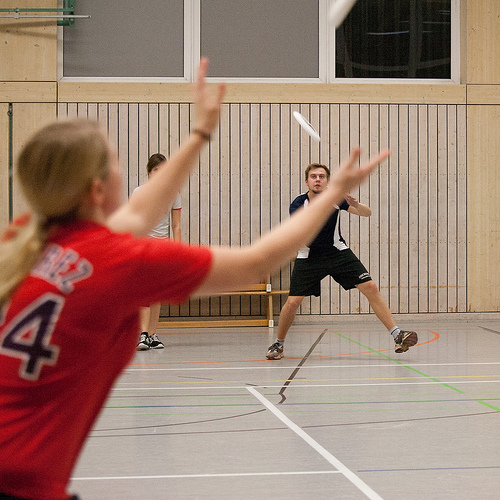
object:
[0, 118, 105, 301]
hair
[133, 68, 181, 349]
woman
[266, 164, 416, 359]
man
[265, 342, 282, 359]
foot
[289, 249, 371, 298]
short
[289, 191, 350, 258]
top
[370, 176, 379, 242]
bicept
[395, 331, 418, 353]
shoe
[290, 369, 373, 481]
part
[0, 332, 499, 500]
floor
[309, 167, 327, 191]
face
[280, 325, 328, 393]
line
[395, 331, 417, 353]
sole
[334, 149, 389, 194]
hand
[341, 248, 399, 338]
leg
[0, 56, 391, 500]
lady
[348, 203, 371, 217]
part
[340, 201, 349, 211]
bicep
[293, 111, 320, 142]
dish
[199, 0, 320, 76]
window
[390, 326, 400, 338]
sock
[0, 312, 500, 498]
court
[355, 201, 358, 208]
band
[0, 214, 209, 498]
jersey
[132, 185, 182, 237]
shirt